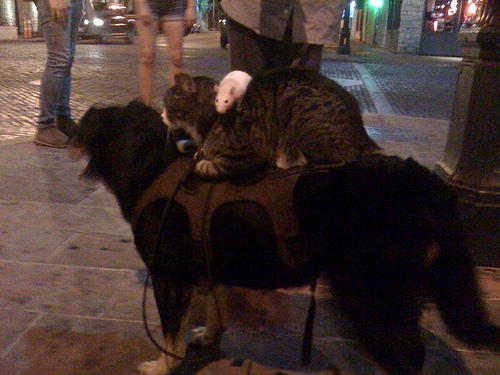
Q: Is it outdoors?
A: Yes, it is outdoors.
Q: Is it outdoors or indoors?
A: It is outdoors.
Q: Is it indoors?
A: No, it is outdoors.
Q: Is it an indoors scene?
A: No, it is outdoors.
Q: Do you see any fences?
A: No, there are no fences.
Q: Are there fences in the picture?
A: No, there are no fences.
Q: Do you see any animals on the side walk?
A: Yes, there are animals on the side walk.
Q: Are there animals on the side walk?
A: Yes, there are animals on the side walk.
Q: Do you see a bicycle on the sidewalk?
A: No, there are animals on the sidewalk.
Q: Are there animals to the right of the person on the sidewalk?
A: Yes, there are animals to the right of the person.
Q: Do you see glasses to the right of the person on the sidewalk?
A: No, there are animals to the right of the person.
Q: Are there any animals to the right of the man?
A: Yes, there are animals to the right of the man.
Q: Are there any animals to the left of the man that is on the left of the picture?
A: No, the animals are to the right of the man.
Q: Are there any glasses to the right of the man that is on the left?
A: No, there are animals to the right of the man.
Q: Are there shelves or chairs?
A: No, there are no shelves or chairs.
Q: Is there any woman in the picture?
A: Yes, there is a woman.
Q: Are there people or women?
A: Yes, there is a woman.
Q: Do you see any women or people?
A: Yes, there is a woman.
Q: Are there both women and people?
A: Yes, there are both a woman and people.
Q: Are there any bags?
A: No, there are no bags.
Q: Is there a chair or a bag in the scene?
A: No, there are no bags or chairs.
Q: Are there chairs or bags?
A: No, there are no bags or chairs.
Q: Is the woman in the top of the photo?
A: Yes, the woman is in the top of the image.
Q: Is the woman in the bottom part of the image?
A: No, the woman is in the top of the image.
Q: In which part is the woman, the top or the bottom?
A: The woman is in the top of the image.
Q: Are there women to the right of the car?
A: Yes, there is a woman to the right of the car.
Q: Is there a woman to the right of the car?
A: Yes, there is a woman to the right of the car.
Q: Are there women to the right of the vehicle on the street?
A: Yes, there is a woman to the right of the car.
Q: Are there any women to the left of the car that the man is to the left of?
A: No, the woman is to the right of the car.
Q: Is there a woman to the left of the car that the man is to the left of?
A: No, the woman is to the right of the car.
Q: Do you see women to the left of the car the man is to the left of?
A: No, the woman is to the right of the car.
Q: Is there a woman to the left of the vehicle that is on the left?
A: No, the woman is to the right of the car.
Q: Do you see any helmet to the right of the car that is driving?
A: No, there is a woman to the right of the car.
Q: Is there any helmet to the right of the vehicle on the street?
A: No, there is a woman to the right of the car.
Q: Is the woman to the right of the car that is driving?
A: Yes, the woman is to the right of the car.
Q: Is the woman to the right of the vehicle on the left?
A: Yes, the woman is to the right of the car.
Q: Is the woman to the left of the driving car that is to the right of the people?
A: No, the woman is to the right of the car.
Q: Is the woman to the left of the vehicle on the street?
A: No, the woman is to the right of the car.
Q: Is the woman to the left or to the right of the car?
A: The woman is to the right of the car.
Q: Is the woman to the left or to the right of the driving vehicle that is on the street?
A: The woman is to the right of the car.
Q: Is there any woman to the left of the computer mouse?
A: Yes, there is a woman to the left of the computer mouse.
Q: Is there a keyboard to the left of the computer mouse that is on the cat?
A: No, there is a woman to the left of the mouse.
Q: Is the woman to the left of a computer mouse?
A: Yes, the woman is to the left of a computer mouse.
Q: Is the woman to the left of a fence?
A: No, the woman is to the left of a computer mouse.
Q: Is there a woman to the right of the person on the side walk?
A: Yes, there is a woman to the right of the person.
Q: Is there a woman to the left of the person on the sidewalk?
A: No, the woman is to the right of the person.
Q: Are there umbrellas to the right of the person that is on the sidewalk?
A: No, there is a woman to the right of the person.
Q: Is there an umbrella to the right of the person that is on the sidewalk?
A: No, there is a woman to the right of the person.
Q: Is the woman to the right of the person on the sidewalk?
A: Yes, the woman is to the right of the person.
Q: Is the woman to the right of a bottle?
A: No, the woman is to the right of the person.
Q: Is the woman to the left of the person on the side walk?
A: No, the woman is to the right of the person.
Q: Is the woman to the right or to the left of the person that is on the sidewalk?
A: The woman is to the right of the person.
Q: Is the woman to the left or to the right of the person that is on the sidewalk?
A: The woman is to the right of the person.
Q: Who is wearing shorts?
A: The woman is wearing shorts.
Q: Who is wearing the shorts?
A: The woman is wearing shorts.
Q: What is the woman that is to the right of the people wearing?
A: The woman is wearing shorts.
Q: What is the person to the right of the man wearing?
A: The woman is wearing shorts.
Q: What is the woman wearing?
A: The woman is wearing shorts.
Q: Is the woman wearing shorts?
A: Yes, the woman is wearing shorts.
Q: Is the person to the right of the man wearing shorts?
A: Yes, the woman is wearing shorts.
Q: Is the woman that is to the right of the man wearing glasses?
A: No, the woman is wearing shorts.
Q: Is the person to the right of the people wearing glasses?
A: No, the woman is wearing shorts.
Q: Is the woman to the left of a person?
A: Yes, the woman is to the left of a person.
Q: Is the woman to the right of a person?
A: No, the woman is to the left of a person.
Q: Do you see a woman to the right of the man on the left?
A: Yes, there is a woman to the right of the man.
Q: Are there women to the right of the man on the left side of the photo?
A: Yes, there is a woman to the right of the man.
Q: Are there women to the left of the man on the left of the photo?
A: No, the woman is to the right of the man.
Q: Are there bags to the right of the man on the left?
A: No, there is a woman to the right of the man.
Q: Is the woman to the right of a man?
A: Yes, the woman is to the right of a man.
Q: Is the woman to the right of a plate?
A: No, the woman is to the right of a man.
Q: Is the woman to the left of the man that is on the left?
A: No, the woman is to the right of the man.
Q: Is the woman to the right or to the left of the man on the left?
A: The woman is to the right of the man.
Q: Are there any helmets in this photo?
A: No, there are no helmets.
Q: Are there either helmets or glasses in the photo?
A: No, there are no helmets or glasses.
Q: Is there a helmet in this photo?
A: No, there are no helmets.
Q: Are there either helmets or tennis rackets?
A: No, there are no helmets or tennis rackets.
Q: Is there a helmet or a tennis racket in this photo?
A: No, there are no helmets or rackets.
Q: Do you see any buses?
A: No, there are no buses.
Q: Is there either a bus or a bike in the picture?
A: No, there are no buses or bikes.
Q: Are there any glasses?
A: No, there are no glasses.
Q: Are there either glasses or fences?
A: No, there are no glasses or fences.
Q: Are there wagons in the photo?
A: No, there are no wagons.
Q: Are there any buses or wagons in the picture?
A: No, there are no wagons or buses.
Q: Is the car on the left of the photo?
A: Yes, the car is on the left of the image.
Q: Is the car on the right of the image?
A: No, the car is on the left of the image.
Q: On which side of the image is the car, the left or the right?
A: The car is on the left of the image.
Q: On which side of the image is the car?
A: The car is on the left of the image.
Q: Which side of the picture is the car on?
A: The car is on the left of the image.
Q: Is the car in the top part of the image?
A: Yes, the car is in the top of the image.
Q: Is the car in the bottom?
A: No, the car is in the top of the image.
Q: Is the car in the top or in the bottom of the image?
A: The car is in the top of the image.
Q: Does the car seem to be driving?
A: Yes, the car is driving.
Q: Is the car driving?
A: Yes, the car is driving.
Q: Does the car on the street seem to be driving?
A: Yes, the car is driving.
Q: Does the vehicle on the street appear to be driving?
A: Yes, the car is driving.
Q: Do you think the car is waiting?
A: No, the car is driving.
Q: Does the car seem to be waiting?
A: No, the car is driving.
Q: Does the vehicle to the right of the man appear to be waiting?
A: No, the car is driving.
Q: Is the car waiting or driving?
A: The car is driving.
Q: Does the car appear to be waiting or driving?
A: The car is driving.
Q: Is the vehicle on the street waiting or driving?
A: The car is driving.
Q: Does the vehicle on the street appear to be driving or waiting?
A: The car is driving.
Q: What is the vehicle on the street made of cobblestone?
A: The vehicle is a car.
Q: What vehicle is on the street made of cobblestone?
A: The vehicle is a car.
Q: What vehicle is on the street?
A: The vehicle is a car.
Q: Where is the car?
A: The car is on the street.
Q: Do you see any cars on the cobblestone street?
A: Yes, there is a car on the street.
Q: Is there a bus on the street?
A: No, there is a car on the street.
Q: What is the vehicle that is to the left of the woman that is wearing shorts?
A: The vehicle is a car.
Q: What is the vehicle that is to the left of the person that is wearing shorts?
A: The vehicle is a car.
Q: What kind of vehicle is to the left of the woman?
A: The vehicle is a car.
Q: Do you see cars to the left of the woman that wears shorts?
A: Yes, there is a car to the left of the woman.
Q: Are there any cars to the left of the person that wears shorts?
A: Yes, there is a car to the left of the woman.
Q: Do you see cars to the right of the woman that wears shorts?
A: No, the car is to the left of the woman.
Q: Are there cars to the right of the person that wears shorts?
A: No, the car is to the left of the woman.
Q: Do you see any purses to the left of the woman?
A: No, there is a car to the left of the woman.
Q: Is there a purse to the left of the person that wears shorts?
A: No, there is a car to the left of the woman.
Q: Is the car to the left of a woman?
A: Yes, the car is to the left of a woman.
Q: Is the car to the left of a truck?
A: No, the car is to the left of a woman.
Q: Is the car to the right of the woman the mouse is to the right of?
A: No, the car is to the left of the woman.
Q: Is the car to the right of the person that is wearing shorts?
A: No, the car is to the left of the woman.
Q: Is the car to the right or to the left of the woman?
A: The car is to the left of the woman.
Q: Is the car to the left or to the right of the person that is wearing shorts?
A: The car is to the left of the woman.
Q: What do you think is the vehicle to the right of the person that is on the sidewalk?
A: The vehicle is a car.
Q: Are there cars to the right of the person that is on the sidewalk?
A: Yes, there is a car to the right of the person.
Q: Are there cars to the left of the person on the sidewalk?
A: No, the car is to the right of the person.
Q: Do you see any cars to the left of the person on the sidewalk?
A: No, the car is to the right of the person.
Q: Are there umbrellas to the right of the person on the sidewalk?
A: No, there is a car to the right of the person.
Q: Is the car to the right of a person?
A: Yes, the car is to the right of a person.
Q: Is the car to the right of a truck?
A: No, the car is to the right of a person.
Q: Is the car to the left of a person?
A: No, the car is to the right of a person.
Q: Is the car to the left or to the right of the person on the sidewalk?
A: The car is to the right of the person.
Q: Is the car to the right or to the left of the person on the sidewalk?
A: The car is to the right of the person.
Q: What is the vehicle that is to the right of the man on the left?
A: The vehicle is a car.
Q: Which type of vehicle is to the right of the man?
A: The vehicle is a car.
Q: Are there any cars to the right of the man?
A: Yes, there is a car to the right of the man.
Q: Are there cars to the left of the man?
A: No, the car is to the right of the man.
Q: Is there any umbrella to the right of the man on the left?
A: No, there is a car to the right of the man.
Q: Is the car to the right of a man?
A: Yes, the car is to the right of a man.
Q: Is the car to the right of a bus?
A: No, the car is to the right of a man.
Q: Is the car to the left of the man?
A: No, the car is to the right of the man.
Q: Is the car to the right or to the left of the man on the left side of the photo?
A: The car is to the right of the man.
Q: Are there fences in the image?
A: No, there are no fences.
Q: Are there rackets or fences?
A: No, there are no fences or rackets.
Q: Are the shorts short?
A: Yes, the shorts are short.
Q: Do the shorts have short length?
A: Yes, the shorts are short.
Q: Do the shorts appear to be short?
A: Yes, the shorts are short.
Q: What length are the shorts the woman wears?
A: The shorts are short.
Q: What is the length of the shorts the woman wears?
A: The shorts are short.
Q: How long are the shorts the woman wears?
A: The shorts are short.